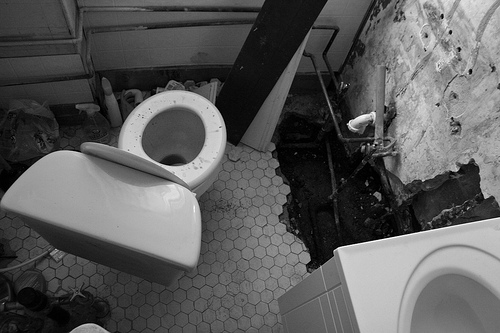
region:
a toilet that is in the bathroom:
[107, 53, 398, 329]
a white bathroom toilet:
[23, 70, 345, 322]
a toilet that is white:
[75, 82, 278, 272]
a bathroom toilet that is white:
[33, 76, 260, 323]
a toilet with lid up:
[51, 71, 319, 315]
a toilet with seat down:
[125, 80, 258, 295]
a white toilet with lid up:
[26, 70, 293, 300]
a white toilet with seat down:
[82, 75, 283, 301]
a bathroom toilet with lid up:
[41, 55, 340, 314]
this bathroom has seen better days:
[243, 0, 498, 265]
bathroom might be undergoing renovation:
[4, 14, 491, 331]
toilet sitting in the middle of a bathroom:
[6, 75, 228, 280]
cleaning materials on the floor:
[69, 70, 128, 141]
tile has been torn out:
[266, 64, 412, 267]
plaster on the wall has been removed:
[336, 0, 497, 212]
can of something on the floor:
[13, 282, 75, 330]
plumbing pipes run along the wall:
[5, 5, 265, 70]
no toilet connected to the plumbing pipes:
[271, 33, 441, 259]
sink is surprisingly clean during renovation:
[272, 210, 498, 330]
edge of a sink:
[324, 279, 329, 289]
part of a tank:
[149, 226, 160, 244]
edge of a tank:
[162, 223, 172, 237]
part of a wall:
[427, 82, 432, 87]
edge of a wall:
[247, 209, 258, 228]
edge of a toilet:
[203, 170, 204, 171]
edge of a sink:
[367, 295, 371, 301]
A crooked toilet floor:
[272, 185, 343, 249]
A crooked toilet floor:
[344, 175, 418, 235]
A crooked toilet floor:
[297, 121, 357, 193]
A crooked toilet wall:
[402, 156, 474, 233]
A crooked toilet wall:
[365, 25, 468, 137]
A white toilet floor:
[147, 280, 211, 331]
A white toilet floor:
[230, 157, 275, 231]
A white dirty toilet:
[49, 98, 220, 305]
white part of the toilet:
[113, 93, 253, 166]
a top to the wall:
[333, 94, 375, 145]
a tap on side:
[333, 93, 396, 158]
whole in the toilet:
[151, 135, 192, 165]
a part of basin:
[313, 214, 403, 331]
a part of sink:
[331, 243, 393, 330]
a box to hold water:
[17, 154, 252, 258]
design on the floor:
[236, 229, 275, 262]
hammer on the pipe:
[363, 65, 400, 164]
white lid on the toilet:
[60, 121, 219, 206]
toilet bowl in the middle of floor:
[0, 68, 286, 328]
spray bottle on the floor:
[70, 97, 110, 139]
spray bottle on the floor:
[97, 66, 125, 133]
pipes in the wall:
[313, 20, 396, 166]